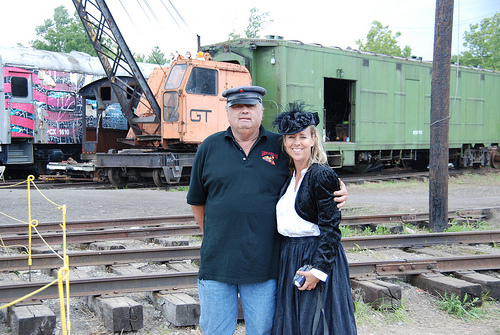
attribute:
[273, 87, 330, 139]
hat — black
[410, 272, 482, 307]
block — wooden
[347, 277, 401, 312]
block — wooden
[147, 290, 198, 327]
block — wooden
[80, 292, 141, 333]
block — wooden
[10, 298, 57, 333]
block — wooden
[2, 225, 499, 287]
track — empty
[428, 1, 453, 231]
pole — wood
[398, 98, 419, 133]
train — green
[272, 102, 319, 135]
hat — black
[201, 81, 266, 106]
hat — leather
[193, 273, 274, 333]
jeans — blue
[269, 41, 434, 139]
train car — green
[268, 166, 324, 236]
shirt — white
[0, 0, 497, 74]
sky — blue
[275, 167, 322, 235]
blouse — white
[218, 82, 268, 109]
black hat — man's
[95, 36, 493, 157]
train — green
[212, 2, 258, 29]
sky — blue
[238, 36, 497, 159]
train car — green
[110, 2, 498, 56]
sky — blue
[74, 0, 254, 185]
crane — yellow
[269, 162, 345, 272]
jacket — black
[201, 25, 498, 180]
train car — green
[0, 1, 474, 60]
clouds — white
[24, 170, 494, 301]
tracks — train